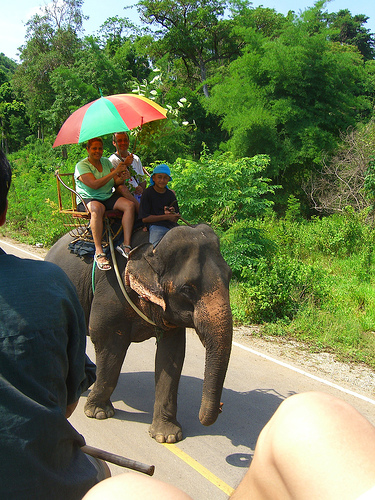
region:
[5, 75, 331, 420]
people riding on an elephant.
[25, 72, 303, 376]
some people riding on an elephant.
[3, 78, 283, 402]
group of people riding on an elephant.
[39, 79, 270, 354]
people riding an elephant on sunny day.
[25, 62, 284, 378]
some people riding an elephant on sunny day.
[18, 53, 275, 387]
group of people riding an elephant on sunny day.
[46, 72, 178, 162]
people under an umbrella.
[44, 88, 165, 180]
people under an umbrella on sunny day.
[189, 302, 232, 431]
trunk of an elephant.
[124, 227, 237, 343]
head of a mighty elephant.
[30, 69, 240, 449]
A family sits on elephant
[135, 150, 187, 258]
Boy wears a blue cap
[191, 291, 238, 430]
Long trunk of elephant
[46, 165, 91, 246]
Small bench on back of elephant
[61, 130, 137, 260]
Woman wears green t-shirt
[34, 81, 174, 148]
Umbrella is red, green and yellow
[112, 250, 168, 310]
Ear of elephant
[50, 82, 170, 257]
Person holds an umbrella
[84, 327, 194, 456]
Front legs of elephant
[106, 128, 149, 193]
Man wears white shirt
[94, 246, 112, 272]
A womans sandal.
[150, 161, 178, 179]
A blue hat.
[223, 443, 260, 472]
A shadow on the ground.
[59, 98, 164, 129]
Multi color umbrella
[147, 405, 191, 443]
An elephants foot.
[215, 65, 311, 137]
green leaves from a tree.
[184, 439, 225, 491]
Yellow line on the road.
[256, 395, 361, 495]
Someone's leg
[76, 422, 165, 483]
A man holding a stick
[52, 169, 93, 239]
A seat on top of an elephant.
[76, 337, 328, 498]
elephant shadow on pavement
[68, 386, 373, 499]
Two knees of a white person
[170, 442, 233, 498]
Road is painted with a yellow line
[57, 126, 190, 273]
Family riding an elephant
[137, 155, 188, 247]
Little boy wears a blue hat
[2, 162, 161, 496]
Man hold a stick on right side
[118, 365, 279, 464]
Shadow of elephant cast on the road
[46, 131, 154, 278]
Couple sits on a bench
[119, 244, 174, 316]
Left ears of an elephant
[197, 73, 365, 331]
Bushes on left side of road